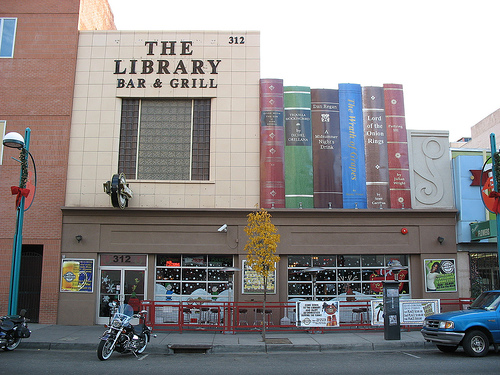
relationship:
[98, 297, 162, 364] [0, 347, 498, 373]
motorcycle standing in street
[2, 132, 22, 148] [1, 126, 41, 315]
street light mounted on pole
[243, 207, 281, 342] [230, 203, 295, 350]
leaves part of tree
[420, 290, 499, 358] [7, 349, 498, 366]
blue truck parked on road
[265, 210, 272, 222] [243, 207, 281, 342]
leaf part of leaves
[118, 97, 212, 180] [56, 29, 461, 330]
window part of building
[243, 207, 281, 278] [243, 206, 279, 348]
leaves part of tree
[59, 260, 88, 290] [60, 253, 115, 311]
mug displayed on poster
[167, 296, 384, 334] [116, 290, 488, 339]
stools set by outdoor counter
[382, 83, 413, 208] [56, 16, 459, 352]
book depicted on building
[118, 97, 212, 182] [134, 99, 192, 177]
window made of tiles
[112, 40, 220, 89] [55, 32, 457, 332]
name below establishment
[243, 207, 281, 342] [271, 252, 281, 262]
leaves has yellow leaf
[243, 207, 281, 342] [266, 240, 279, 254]
leaves has yellow leaf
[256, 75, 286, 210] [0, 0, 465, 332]
book on wall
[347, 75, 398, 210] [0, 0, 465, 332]
book on wall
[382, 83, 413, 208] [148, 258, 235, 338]
book on wall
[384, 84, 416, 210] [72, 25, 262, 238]
book on wall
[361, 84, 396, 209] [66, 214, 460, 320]
book on wall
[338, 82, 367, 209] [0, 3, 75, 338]
book on wall